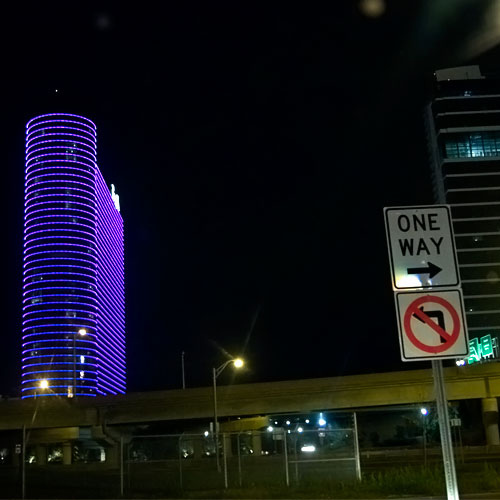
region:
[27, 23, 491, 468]
city skyscrapers at night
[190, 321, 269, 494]
streetlight at night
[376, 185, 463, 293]
black and white one way sign with arrow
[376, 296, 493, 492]
black white and red no left turn sign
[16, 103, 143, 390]
building with purple lights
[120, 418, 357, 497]
metal fence in front of skyline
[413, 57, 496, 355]
black and white skyscraper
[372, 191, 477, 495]
street sign in front of skyscrapers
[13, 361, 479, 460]
city overpass in front of skyscrapers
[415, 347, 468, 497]
silver metal pole for street signs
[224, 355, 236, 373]
yellow light is spotted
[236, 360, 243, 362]
yellow light is spotted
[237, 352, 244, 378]
yellow light is spotted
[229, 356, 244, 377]
yellow light is spotted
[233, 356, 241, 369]
yellow light is spotted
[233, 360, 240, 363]
yellow light is spotted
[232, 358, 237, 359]
yellow light is spotted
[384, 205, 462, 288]
A one way sign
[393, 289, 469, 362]
A no left turn sign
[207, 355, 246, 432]
A street lamp post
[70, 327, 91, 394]
A street lamp post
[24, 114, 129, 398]
A building with glowing bright blue lights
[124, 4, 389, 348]
Clear dark night sky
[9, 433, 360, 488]
A metal chain link fence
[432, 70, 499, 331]
A building with one story lit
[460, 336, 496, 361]
Green highway signs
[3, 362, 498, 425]
A roadway bridge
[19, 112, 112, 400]
Neon blue lit high-rise building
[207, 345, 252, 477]
Street lamp on top of tall metal pole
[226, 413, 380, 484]
Six foot chain link fence and gait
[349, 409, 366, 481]
Six foot tall aluminum fence post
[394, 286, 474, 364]
Red, black, and white no left turn sign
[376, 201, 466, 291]
White sign with black letters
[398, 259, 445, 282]
Top sign has black arrow pointing to the right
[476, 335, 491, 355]
Green highway exit sign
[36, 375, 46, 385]
Light on in room of blue lit skyscraper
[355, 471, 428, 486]
Tall growing patch of green weeds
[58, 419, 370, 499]
A gence around the grass.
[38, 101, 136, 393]
The purple building is lighted up.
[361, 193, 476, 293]
A sign that says "One Way".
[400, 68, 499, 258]
A builidng on the side.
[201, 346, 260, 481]
The street light is on.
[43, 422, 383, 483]
The tall iron fence.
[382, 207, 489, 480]
Two signs on the pole.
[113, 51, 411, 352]
It is dark outside.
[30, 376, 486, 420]
The expressway in front of the buildings.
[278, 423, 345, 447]
Headlights from the cars.